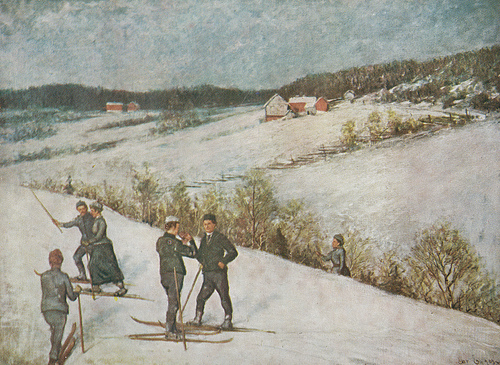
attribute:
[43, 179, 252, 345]
people — skiing, talking, walking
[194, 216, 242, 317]
man — motioning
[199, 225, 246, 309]
suit — dark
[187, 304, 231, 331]
boots — dark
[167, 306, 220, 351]
skiis — brown, wooden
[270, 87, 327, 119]
barn — red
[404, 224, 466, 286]
trees — bare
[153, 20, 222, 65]
clouds — white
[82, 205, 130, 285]
woman — walking, climbing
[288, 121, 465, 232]
field — covered, snowy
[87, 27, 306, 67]
sky — cloudy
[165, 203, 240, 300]
men — standing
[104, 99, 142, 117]
house — red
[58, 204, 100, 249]
man — pointing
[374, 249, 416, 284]
bush — brown